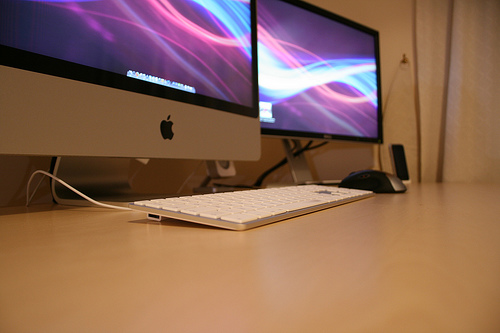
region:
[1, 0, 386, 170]
two macs with big monitors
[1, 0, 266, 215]
this is an imac, could be any generation from the last 5 or 6 years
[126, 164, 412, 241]
1 keyboard+1 mouse for both macs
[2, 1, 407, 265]
setup is probably so the smaller imac can be used exclusively for the photoshop palette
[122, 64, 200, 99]
white words, made blue in a blur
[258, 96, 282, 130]
white icon, looks like ebay, probably isnt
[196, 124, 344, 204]
black cables leading downward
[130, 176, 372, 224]
a white keyboard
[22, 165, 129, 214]
a white cord plugged into the keyboard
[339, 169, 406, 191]
a black computer mouse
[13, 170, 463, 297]
a wooden desk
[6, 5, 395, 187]
computers sitting on a desk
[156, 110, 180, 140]
a black apple emblem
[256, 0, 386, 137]
a screen of a computer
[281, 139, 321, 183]
the stand of the computer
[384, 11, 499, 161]
the wall behind the computer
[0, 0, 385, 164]
Two flat computer screens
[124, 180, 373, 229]
White computer keyboard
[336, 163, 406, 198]
Black and silver computer mouse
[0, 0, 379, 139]
Purple swirled desktop backgrounds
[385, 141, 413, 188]
Silver and black computer speaker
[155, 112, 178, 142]
Black Apple logo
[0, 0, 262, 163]
Large black and white computer screen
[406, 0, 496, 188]
Long white hanging curtains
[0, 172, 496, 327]
Light wood desk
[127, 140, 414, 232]
Three computer accessories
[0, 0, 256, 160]
a computer monitor showing neon streaming lights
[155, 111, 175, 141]
black logo on the monitor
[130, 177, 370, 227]
a white keyboard on a table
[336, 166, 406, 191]
a black mouse on the table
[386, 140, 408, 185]
a speaker on the table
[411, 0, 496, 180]
light colored fabric on the wall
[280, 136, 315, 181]
stand holding the monitor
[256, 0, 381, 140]
a second monitor with same picture on it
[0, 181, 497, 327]
table the computer equipment is on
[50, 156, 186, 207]
monitor stand by the white keyboard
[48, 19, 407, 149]
Two monitors on the table.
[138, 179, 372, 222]
A white keyboard on the table.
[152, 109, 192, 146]
Apple symbol on the monitor.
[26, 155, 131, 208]
White cords from the keyboard to monitor.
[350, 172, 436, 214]
Mouse on the table.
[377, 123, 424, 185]
Speaker next to the monitor.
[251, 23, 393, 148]
The monitor is black.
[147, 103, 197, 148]
The Apple logo is black.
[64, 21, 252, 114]
The monitor is turned on.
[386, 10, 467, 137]
The wall is yellow.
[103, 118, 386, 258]
white keyboard on a table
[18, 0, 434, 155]
two monitors on table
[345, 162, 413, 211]
mouse next to keyboard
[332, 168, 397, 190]
black and silver mouse